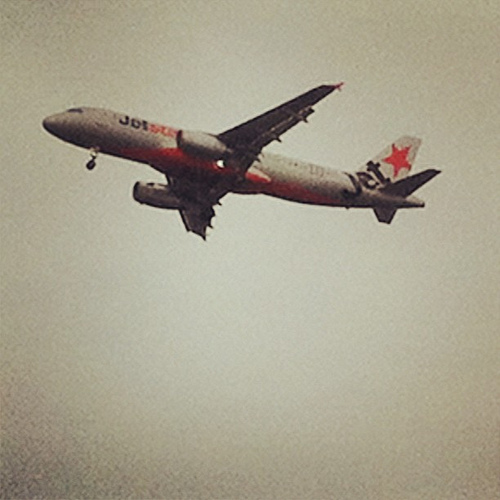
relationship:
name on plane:
[115, 111, 180, 141] [36, 31, 497, 305]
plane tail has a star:
[359, 131, 442, 228] [382, 140, 413, 177]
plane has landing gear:
[40, 81, 442, 244] [80, 143, 107, 177]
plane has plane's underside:
[40, 81, 442, 244] [58, 131, 413, 208]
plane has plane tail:
[46, 75, 441, 244] [359, 131, 442, 228]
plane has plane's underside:
[46, 75, 441, 244] [58, 131, 413, 208]